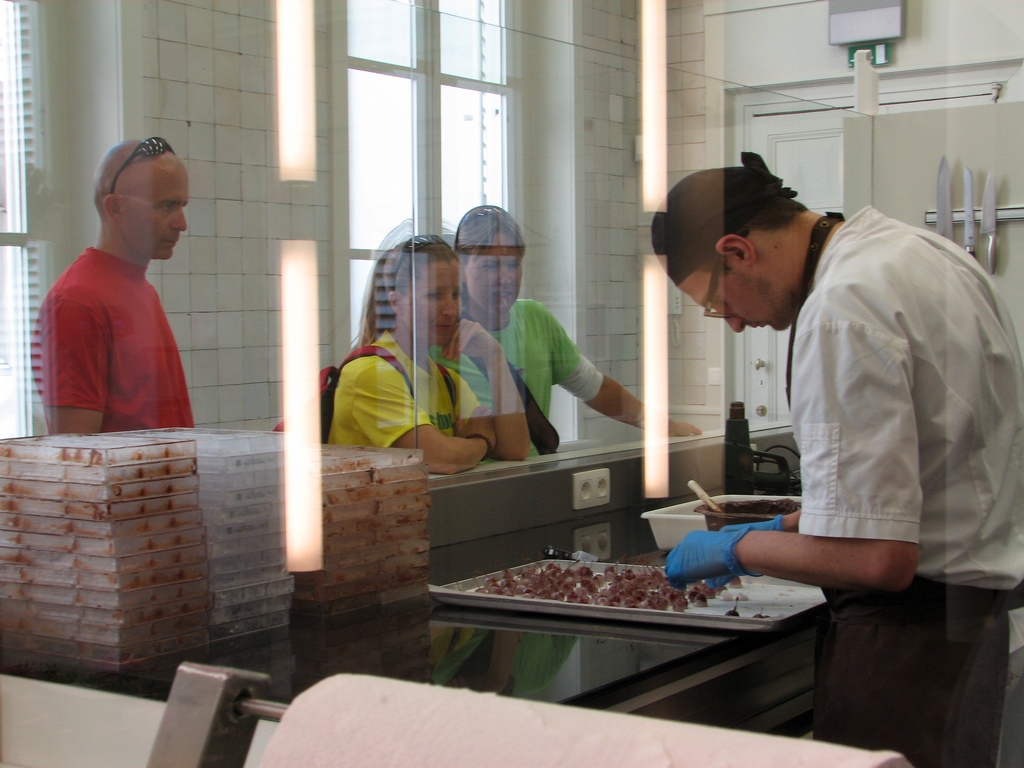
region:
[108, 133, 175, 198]
Black pair of sunglasses on a bald mans head.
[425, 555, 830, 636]
Tray of food a man is working at.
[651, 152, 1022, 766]
A man with black head wrap and blue gloves.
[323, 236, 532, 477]
Woman in yellow with backpack on.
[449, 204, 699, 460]
Brown haired woman in a green shirt.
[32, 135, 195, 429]
Bald man standing in a red shirt.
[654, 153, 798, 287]
A black head wrap.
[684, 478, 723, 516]
White handle coming out of a bowl of chocolate.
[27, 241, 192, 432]
Man wearing red shirt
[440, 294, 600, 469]
Woman wearing green shirt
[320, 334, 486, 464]
Woman wearing yellow shirt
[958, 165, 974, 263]
Knife hanging on the wall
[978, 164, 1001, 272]
Knife hanging on the wall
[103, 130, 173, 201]
Man is wearing glasses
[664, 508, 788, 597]
Man is wearing blue gloves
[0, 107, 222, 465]
man is wearing red shirt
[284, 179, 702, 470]
two girls watching something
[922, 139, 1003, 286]
silver knifes on the wall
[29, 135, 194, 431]
the man wearing a red shirt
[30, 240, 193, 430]
the shirt is red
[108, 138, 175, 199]
the sunglasses are black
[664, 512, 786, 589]
the gloves are blue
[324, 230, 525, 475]
the woman is wearing a yellow shirt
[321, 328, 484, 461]
the shirt is yellow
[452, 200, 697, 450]
the woman wearing a green shirt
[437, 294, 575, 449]
the shirt is green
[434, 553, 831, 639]
the food on the silver tray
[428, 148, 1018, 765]
the man in front of the silver tray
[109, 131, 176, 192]
sunglasses worn by human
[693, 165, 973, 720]
a persont standing inside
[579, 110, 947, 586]
a person wearing a hat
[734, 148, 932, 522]
a perosn wearing a shirt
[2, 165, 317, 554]
a person wearing red shirt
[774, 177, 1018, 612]
man wearing a white shirt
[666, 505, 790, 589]
man wearing blue gloves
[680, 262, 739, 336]
man wearing reading glasses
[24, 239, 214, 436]
man wearing a red shirt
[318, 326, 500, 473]
woman wearing a yellow shirt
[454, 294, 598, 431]
woman wearing a green shirt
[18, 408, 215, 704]
food stacked in plastic trays on the counter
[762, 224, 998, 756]
man wearing a black apron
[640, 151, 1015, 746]
the man is preparing food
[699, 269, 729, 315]
the man is wearing glasses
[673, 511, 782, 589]
the gloves are blue in color